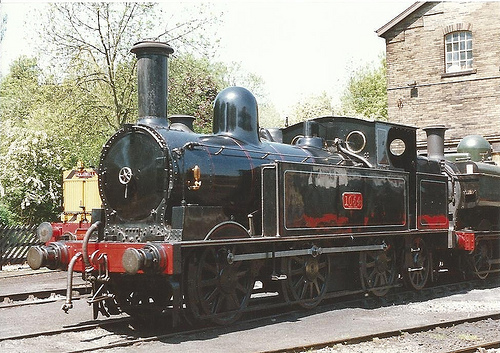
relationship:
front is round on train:
[96, 121, 179, 222] [25, 36, 498, 334]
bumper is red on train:
[27, 240, 176, 280] [25, 36, 498, 334]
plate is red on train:
[336, 187, 365, 214] [25, 36, 498, 334]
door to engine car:
[388, 124, 418, 231] [26, 39, 456, 314]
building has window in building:
[439, 30, 480, 75] [359, 99, 491, 129]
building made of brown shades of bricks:
[379, 49, 489, 83] [428, 165, 459, 195]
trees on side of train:
[13, 101, 109, 263] [72, 162, 484, 286]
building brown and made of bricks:
[375, 0, 500, 131] [375, 104, 463, 145]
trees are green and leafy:
[7, 68, 94, 217] [20, 141, 93, 243]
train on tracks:
[96, 111, 497, 310] [0, 267, 491, 348]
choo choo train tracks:
[5, 257, 482, 353] [30, 280, 468, 321]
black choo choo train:
[84, 162, 495, 260] [77, 88, 488, 326]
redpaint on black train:
[74, 258, 179, 353] [199, 114, 472, 224]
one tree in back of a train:
[349, 99, 389, 180] [62, 146, 484, 315]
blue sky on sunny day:
[231, 174, 335, 214] [6, 100, 430, 141]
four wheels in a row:
[116, 257, 482, 321] [147, 243, 474, 353]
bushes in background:
[23, 101, 161, 220] [16, 71, 497, 123]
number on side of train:
[317, 160, 432, 285] [55, 145, 498, 303]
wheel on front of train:
[107, 286, 278, 353] [85, 167, 495, 282]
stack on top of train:
[52, 195, 398, 353] [61, 124, 496, 346]